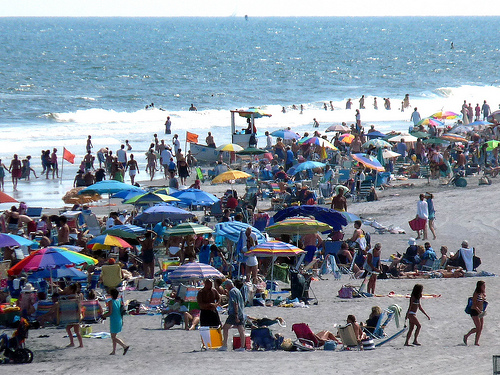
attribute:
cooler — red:
[229, 330, 253, 351]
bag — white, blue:
[360, 336, 376, 349]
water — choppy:
[2, 16, 497, 210]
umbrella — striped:
[167, 258, 223, 280]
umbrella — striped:
[213, 219, 263, 247]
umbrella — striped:
[437, 131, 468, 144]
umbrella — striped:
[420, 109, 462, 121]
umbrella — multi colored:
[6, 240, 95, 295]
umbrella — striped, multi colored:
[246, 236, 306, 304]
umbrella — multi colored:
[211, 220, 261, 247]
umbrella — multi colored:
[163, 259, 222, 289]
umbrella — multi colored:
[350, 147, 386, 175]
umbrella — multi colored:
[83, 233, 133, 253]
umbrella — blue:
[76, 177, 142, 197]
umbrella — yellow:
[211, 166, 249, 196]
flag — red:
[55, 146, 76, 185]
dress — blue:
[105, 297, 123, 334]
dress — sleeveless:
[107, 292, 121, 335]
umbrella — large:
[212, 168, 251, 199]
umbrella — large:
[264, 210, 334, 256]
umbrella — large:
[75, 173, 142, 213]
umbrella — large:
[139, 197, 197, 218]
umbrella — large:
[161, 221, 215, 239]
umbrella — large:
[248, 232, 308, 282]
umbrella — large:
[159, 250, 229, 284]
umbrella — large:
[77, 229, 137, 254]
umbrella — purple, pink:
[155, 251, 227, 285]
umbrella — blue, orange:
[235, 234, 309, 264]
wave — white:
[55, 94, 484, 134]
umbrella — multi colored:
[4, 242, 107, 274]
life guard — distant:
[226, 104, 271, 153]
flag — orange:
[57, 144, 78, 178]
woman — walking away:
[397, 274, 433, 350]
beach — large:
[8, 120, 498, 369]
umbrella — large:
[73, 175, 145, 198]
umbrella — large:
[79, 174, 140, 197]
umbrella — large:
[6, 241, 98, 273]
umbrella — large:
[79, 228, 131, 251]